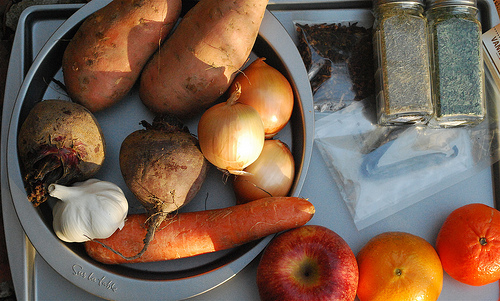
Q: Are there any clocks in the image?
A: No, there are no clocks.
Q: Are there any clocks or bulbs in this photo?
A: No, there are no clocks or bulbs.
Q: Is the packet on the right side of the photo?
A: Yes, the packet is on the right of the image.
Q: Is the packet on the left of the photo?
A: No, the packet is on the right of the image.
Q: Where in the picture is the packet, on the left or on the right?
A: The packet is on the right of the image.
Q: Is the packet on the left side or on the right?
A: The packet is on the right of the image.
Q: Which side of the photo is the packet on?
A: The packet is on the right of the image.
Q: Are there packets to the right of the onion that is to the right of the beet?
A: Yes, there is a packet to the right of the onion.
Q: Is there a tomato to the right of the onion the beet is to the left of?
A: No, there is a packet to the right of the onion.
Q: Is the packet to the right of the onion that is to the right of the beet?
A: Yes, the packet is to the right of the onion.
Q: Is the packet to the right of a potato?
A: No, the packet is to the right of the onion.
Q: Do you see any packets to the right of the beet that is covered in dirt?
A: Yes, there is a packet to the right of the beet.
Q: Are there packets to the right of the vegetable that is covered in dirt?
A: Yes, there is a packet to the right of the beet.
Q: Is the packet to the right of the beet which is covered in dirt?
A: Yes, the packet is to the right of the beet.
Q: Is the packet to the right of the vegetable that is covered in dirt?
A: Yes, the packet is to the right of the beet.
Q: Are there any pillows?
A: No, there are no pillows.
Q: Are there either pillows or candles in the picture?
A: No, there are no pillows or candles.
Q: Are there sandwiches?
A: No, there are no sandwiches.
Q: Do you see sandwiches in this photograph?
A: No, there are no sandwiches.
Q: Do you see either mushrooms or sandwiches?
A: No, there are no sandwiches or mushrooms.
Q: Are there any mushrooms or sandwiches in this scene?
A: No, there are no sandwiches or mushrooms.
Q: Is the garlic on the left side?
A: Yes, the garlic is on the left of the image.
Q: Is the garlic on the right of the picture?
A: No, the garlic is on the left of the image.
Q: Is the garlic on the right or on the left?
A: The garlic is on the left of the image.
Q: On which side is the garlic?
A: The garlic is on the left of the image.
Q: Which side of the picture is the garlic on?
A: The garlic is on the left of the image.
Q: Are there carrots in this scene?
A: Yes, there is a carrot.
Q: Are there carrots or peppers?
A: Yes, there is a carrot.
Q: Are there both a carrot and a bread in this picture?
A: No, there is a carrot but no breads.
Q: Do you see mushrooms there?
A: No, there are no mushrooms.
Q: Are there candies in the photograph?
A: No, there are no candies.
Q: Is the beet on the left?
A: Yes, the beet is on the left of the image.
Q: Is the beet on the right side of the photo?
A: No, the beet is on the left of the image.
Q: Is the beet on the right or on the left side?
A: The beet is on the left of the image.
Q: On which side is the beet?
A: The beet is on the left of the image.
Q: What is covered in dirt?
A: The beet is covered in dirt.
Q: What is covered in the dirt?
A: The beet is covered in dirt.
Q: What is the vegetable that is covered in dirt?
A: The vegetable is a beet.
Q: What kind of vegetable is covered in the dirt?
A: The vegetable is a beet.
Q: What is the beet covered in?
A: The beet is covered in dirt.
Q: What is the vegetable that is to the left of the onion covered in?
A: The beet is covered in dirt.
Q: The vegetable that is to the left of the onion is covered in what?
A: The beet is covered in dirt.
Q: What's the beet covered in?
A: The beet is covered in dirt.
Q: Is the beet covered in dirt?
A: Yes, the beet is covered in dirt.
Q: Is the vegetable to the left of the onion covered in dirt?
A: Yes, the beet is covered in dirt.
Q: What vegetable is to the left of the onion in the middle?
A: The vegetable is a beet.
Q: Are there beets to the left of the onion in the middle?
A: Yes, there is a beet to the left of the onion.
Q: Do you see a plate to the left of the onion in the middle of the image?
A: No, there is a beet to the left of the onion.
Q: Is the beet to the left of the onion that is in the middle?
A: Yes, the beet is to the left of the onion.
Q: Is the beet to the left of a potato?
A: No, the beet is to the left of the onion.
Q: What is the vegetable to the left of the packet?
A: The vegetable is a beet.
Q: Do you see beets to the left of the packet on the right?
A: Yes, there is a beet to the left of the packet.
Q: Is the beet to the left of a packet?
A: Yes, the beet is to the left of a packet.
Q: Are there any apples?
A: Yes, there is an apple.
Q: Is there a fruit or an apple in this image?
A: Yes, there is an apple.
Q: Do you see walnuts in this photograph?
A: No, there are no walnuts.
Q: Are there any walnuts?
A: No, there are no walnuts.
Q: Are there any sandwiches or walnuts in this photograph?
A: No, there are no walnuts or sandwiches.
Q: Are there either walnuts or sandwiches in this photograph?
A: No, there are no walnuts or sandwiches.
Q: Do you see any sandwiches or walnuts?
A: No, there are no walnuts or sandwiches.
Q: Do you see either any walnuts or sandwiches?
A: No, there are no walnuts or sandwiches.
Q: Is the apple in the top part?
A: No, the apple is in the bottom of the image.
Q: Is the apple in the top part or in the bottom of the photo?
A: The apple is in the bottom of the image.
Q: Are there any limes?
A: No, there are no limes.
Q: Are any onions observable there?
A: Yes, there is an onion.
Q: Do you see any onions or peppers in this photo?
A: Yes, there is an onion.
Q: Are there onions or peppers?
A: Yes, there is an onion.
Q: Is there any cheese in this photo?
A: No, there is no cheese.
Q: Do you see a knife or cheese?
A: No, there are no cheese or knives.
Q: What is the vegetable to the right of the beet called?
A: The vegetable is an onion.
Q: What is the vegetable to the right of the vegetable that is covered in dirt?
A: The vegetable is an onion.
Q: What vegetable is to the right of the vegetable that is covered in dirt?
A: The vegetable is an onion.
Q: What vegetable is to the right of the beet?
A: The vegetable is an onion.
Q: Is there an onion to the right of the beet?
A: Yes, there is an onion to the right of the beet.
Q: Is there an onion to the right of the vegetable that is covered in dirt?
A: Yes, there is an onion to the right of the beet.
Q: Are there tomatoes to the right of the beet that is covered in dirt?
A: No, there is an onion to the right of the beet.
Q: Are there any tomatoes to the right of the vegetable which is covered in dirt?
A: No, there is an onion to the right of the beet.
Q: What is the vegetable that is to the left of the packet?
A: The vegetable is an onion.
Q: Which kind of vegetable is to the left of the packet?
A: The vegetable is an onion.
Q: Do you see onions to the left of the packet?
A: Yes, there is an onion to the left of the packet.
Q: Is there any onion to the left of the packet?
A: Yes, there is an onion to the left of the packet.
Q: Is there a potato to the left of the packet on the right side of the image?
A: No, there is an onion to the left of the packet.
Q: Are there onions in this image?
A: Yes, there is an onion.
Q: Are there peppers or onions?
A: Yes, there is an onion.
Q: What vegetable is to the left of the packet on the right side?
A: The vegetable is an onion.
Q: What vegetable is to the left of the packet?
A: The vegetable is an onion.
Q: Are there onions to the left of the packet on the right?
A: Yes, there is an onion to the left of the packet.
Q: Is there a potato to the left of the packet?
A: No, there is an onion to the left of the packet.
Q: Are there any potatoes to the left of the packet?
A: No, there is an onion to the left of the packet.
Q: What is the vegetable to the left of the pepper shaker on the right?
A: The vegetable is an onion.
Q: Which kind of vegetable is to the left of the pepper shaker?
A: The vegetable is an onion.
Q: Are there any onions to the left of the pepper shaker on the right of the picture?
A: Yes, there is an onion to the left of the pepper grinder.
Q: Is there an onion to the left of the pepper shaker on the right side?
A: Yes, there is an onion to the left of the pepper grinder.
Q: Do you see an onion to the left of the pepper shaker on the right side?
A: Yes, there is an onion to the left of the pepper grinder.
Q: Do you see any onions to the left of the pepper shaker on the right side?
A: Yes, there is an onion to the left of the pepper grinder.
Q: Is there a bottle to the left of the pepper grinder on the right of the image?
A: No, there is an onion to the left of the pepper shaker.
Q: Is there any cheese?
A: No, there is no cheese.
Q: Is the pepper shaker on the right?
A: Yes, the pepper shaker is on the right of the image.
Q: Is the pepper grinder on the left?
A: No, the pepper grinder is on the right of the image.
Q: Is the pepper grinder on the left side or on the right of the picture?
A: The pepper grinder is on the right of the image.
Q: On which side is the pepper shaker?
A: The pepper shaker is on the right of the image.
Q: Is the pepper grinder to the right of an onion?
A: Yes, the pepper grinder is to the right of an onion.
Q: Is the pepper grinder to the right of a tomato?
A: No, the pepper grinder is to the right of an onion.